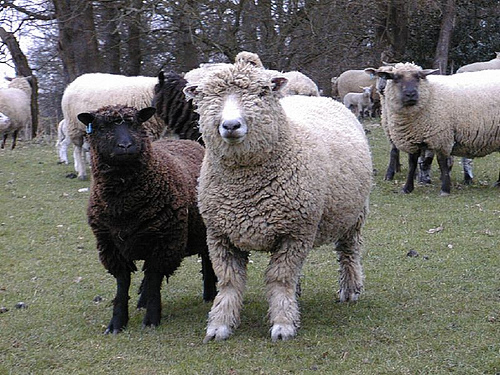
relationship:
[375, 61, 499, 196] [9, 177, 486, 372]
sheep standing in field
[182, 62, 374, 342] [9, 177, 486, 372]
large sheep standing in field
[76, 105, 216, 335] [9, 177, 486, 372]
brown sheep standing in field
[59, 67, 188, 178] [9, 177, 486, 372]
sheep standing in field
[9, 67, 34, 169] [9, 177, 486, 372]
sheep standing in field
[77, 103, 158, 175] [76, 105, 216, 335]
head of brown sheep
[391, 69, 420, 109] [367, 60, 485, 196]
face belonging to sheep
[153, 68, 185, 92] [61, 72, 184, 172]
face belonging to sheep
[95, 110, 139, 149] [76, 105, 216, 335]
face belonging to brown sheep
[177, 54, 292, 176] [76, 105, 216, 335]
sheep head of a brown sheep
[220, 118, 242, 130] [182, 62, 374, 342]
nose of a large sheep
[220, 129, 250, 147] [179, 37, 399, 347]
mouth of a sheep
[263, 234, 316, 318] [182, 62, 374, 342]
leg of a large sheep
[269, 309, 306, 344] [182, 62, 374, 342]
hoof of large sheep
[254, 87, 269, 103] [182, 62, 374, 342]
eye of large sheep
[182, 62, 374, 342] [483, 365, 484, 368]
large sheep looking at camera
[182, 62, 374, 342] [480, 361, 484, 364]
large sheep looking at camera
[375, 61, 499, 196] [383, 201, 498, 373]
sheep in field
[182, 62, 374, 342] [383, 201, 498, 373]
large sheep in field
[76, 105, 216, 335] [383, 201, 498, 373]
brown sheep in field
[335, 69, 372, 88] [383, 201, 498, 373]
sheep in field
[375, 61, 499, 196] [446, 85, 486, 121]
sheep doesnt have wool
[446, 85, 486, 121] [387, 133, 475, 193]
wool on legs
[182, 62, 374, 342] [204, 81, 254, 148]
large sheep has face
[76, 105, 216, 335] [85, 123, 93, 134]
brown sheep has blue tag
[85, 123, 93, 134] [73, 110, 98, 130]
blue tag in ear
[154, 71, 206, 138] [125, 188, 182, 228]
brown sheep has wool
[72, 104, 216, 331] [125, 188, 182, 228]
brown sheep has wool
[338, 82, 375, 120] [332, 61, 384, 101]
sheep next to sheep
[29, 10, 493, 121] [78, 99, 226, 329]
trees behind sheep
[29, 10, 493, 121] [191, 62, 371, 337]
trees behind sheep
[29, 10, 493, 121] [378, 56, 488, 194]
trees behind sheep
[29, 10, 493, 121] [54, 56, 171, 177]
trees behind sheep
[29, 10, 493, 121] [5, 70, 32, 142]
trees behind sheep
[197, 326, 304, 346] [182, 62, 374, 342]
hoofs of large sheep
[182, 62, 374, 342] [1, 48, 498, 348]
large sheep in flock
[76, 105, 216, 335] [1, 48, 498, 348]
brown sheep in flock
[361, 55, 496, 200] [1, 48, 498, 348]
sheep in flock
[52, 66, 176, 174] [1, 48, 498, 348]
sheep in flock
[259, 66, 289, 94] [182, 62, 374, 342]
ear of large sheep